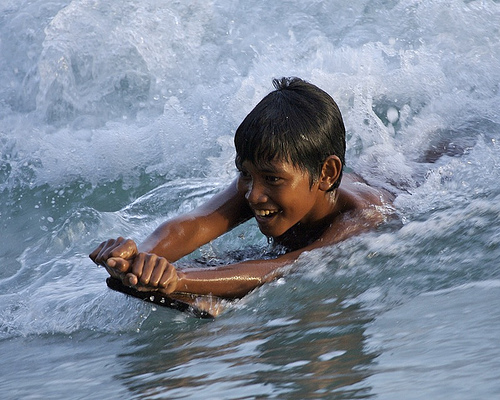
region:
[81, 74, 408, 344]
the boy is wet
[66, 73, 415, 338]
the boy is in the water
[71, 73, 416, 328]
the boy is in the ocean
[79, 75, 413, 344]
the boy is riding a wave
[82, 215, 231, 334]
the boy is holding to something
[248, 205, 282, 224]
the boy is smiling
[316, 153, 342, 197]
this is the boy's ear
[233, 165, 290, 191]
these are the boy's eyes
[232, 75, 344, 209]
the boy has short hair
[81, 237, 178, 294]
these are the boys fingers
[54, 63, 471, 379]
A boy surfing in the ocean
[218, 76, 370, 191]
Wet black hair on the boy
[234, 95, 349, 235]
The boy looks very happy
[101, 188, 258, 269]
Shining wet skin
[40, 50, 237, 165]
The water is very rough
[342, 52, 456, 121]
Thick white sea foam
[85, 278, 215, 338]
A black surfboard beneath the boy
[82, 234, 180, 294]
Two closed fists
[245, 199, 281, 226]
The boy's mouth is open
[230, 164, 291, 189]
The boy's eyes are open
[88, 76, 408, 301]
a boy on a board in the ocean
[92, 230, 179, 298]
a boys hands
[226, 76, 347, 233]
the head of a boy in the ocean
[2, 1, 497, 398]
a large wave in the ocean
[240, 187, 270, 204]
a boys nose on his face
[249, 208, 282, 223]
a smile on a boys face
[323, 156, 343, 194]
a boys ear sticking from his head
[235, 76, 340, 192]
a boys wet hair pasted to his head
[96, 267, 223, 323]
a piece of wood a kid is riding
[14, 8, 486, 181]
frothy ocean water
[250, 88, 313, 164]
boy has dark hair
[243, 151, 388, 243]
boy has brown skin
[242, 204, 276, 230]
boy has light teeth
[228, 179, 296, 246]
boy is smiling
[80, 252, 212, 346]
boy has arms outstretched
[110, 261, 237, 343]
boy is riding surfboard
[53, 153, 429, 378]
boy is in water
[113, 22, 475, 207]
wave is crashing behind boy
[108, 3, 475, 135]
wave makes white foam behind boy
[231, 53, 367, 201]
boy's hair is wet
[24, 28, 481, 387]
A young boy surfing in the ocean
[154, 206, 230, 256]
Shining wet skin on the boy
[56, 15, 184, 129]
Thick white seafoam behind the boy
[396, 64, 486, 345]
The water is very rough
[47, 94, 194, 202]
A wave behind the boy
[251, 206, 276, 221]
White teeth in the boy's mouth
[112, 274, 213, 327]
A black surfboard in the water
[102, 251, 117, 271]
A short thumb nail